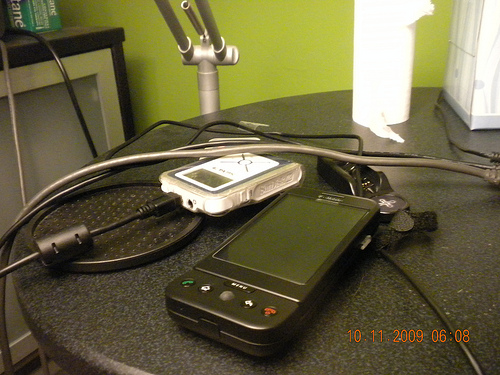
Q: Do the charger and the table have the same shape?
A: Yes, both the charger and the table are round.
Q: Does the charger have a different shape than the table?
A: No, both the charger and the table are round.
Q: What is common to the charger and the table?
A: The shape, both the charger and the table are round.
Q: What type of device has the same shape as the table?
A: The charger is the same shape as the table.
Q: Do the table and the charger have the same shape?
A: Yes, both the table and the charger are round.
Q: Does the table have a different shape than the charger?
A: No, both the table and the charger are round.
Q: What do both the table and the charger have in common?
A: The shape, both the table and the charger are round.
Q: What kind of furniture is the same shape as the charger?
A: The table is the same shape as the charger.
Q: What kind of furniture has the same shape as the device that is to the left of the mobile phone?
A: The table is the same shape as the charger.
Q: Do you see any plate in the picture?
A: No, there are no plates.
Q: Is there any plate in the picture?
A: No, there are no plates.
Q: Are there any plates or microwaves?
A: No, there are no plates or microwaves.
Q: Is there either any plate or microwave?
A: No, there are no plates or microwaves.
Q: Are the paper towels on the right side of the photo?
A: Yes, the paper towels are on the right of the image.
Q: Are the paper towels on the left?
A: No, the paper towels are on the right of the image.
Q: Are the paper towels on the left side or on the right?
A: The paper towels are on the right of the image.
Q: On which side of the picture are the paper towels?
A: The paper towels are on the right of the image.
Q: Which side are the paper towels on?
A: The paper towels are on the right of the image.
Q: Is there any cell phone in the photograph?
A: Yes, there is a cell phone.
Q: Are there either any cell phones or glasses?
A: Yes, there is a cell phone.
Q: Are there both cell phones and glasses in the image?
A: No, there is a cell phone but no glasses.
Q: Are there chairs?
A: No, there are no chairs.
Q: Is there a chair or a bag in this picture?
A: No, there are no chairs or bags.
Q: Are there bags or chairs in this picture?
A: No, there are no chairs or bags.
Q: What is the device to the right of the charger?
A: The device is a cell phone.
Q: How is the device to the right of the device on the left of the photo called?
A: The device is a cell phone.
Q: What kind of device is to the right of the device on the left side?
A: The device is a cell phone.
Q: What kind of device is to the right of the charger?
A: The device is a cell phone.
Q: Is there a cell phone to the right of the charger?
A: Yes, there is a cell phone to the right of the charger.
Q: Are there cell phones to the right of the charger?
A: Yes, there is a cell phone to the right of the charger.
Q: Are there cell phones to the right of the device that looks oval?
A: Yes, there is a cell phone to the right of the charger.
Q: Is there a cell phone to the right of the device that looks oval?
A: Yes, there is a cell phone to the right of the charger.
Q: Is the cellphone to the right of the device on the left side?
A: Yes, the cellphone is to the right of the charger.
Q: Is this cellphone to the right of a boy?
A: No, the cellphone is to the right of the charger.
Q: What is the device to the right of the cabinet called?
A: The device is a cell phone.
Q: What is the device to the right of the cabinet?
A: The device is a cell phone.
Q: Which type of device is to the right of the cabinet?
A: The device is a cell phone.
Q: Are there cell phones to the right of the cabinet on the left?
A: Yes, there is a cell phone to the right of the cabinet.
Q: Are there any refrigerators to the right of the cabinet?
A: No, there is a cell phone to the right of the cabinet.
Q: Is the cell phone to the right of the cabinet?
A: Yes, the cell phone is to the right of the cabinet.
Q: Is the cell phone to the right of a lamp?
A: No, the cell phone is to the right of the cabinet.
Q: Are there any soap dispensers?
A: No, there are no soap dispensers.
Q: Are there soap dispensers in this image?
A: No, there are no soap dispensers.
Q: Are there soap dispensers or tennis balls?
A: No, there are no soap dispensers or tennis balls.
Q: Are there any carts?
A: No, there are no carts.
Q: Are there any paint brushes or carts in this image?
A: No, there are no carts or paint brushes.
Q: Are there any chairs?
A: No, there are no chairs.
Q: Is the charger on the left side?
A: Yes, the charger is on the left of the image.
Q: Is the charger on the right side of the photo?
A: No, the charger is on the left of the image.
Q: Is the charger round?
A: Yes, the charger is round.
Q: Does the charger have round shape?
A: Yes, the charger is round.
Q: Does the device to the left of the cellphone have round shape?
A: Yes, the charger is round.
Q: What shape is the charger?
A: The charger is round.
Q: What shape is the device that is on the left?
A: The charger is round.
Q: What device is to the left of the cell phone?
A: The device is a charger.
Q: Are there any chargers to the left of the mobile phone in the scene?
A: Yes, there is a charger to the left of the mobile phone.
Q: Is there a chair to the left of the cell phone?
A: No, there is a charger to the left of the cell phone.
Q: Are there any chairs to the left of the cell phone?
A: No, there is a charger to the left of the cell phone.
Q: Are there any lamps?
A: No, there are no lamps.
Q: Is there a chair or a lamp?
A: No, there are no lamps or chairs.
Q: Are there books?
A: No, there are no books.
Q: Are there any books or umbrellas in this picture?
A: No, there are no books or umbrellas.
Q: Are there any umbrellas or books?
A: No, there are no books or umbrellas.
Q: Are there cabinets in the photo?
A: Yes, there is a cabinet.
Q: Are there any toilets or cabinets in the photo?
A: Yes, there is a cabinet.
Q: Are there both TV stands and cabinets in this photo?
A: No, there is a cabinet but no TV stands.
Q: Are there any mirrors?
A: No, there are no mirrors.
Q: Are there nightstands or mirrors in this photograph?
A: No, there are no mirrors or nightstands.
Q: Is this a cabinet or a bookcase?
A: This is a cabinet.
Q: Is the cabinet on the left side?
A: Yes, the cabinet is on the left of the image.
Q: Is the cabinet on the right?
A: No, the cabinet is on the left of the image.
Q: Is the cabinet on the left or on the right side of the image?
A: The cabinet is on the left of the image.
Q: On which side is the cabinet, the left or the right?
A: The cabinet is on the left of the image.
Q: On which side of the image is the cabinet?
A: The cabinet is on the left of the image.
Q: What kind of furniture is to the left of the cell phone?
A: The piece of furniture is a cabinet.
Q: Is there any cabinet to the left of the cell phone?
A: Yes, there is a cabinet to the left of the cell phone.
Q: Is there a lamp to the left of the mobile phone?
A: No, there is a cabinet to the left of the mobile phone.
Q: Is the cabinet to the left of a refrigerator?
A: No, the cabinet is to the left of a cell phone.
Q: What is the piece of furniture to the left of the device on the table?
A: The piece of furniture is a cabinet.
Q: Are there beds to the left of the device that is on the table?
A: No, there is a cabinet to the left of the device.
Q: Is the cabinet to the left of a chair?
A: No, the cabinet is to the left of the device.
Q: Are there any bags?
A: No, there are no bags.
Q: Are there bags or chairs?
A: No, there are no bags or chairs.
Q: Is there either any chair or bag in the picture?
A: No, there are no bags or chairs.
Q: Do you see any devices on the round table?
A: Yes, there is a device on the table.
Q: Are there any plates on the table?
A: No, there is a device on the table.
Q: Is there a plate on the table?
A: No, there is a device on the table.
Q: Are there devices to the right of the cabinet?
A: Yes, there is a device to the right of the cabinet.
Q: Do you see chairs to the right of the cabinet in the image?
A: No, there is a device to the right of the cabinet.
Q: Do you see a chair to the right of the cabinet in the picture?
A: No, there is a device to the right of the cabinet.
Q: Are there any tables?
A: Yes, there is a table.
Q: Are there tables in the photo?
A: Yes, there is a table.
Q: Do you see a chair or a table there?
A: Yes, there is a table.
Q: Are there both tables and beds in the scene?
A: No, there is a table but no beds.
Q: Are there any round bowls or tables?
A: Yes, there is a round table.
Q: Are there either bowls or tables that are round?
A: Yes, the table is round.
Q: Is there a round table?
A: Yes, there is a round table.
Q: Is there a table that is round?
A: Yes, there is a table that is round.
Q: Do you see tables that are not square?
A: Yes, there is a round table.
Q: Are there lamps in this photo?
A: No, there are no lamps.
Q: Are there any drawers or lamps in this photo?
A: No, there are no lamps or drawers.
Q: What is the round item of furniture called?
A: The piece of furniture is a table.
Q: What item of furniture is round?
A: The piece of furniture is a table.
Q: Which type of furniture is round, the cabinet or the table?
A: The table is round.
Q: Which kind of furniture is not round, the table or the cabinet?
A: The cabinet is not round.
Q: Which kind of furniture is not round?
A: The furniture is a cabinet.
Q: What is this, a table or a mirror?
A: This is a table.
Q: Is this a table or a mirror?
A: This is a table.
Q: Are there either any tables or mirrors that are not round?
A: No, there is a table but it is round.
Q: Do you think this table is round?
A: Yes, the table is round.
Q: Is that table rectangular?
A: No, the table is round.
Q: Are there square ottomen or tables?
A: No, there is a table but it is round.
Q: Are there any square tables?
A: No, there is a table but it is round.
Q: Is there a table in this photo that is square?
A: No, there is a table but it is round.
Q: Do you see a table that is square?
A: No, there is a table but it is round.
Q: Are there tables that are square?
A: No, there is a table but it is round.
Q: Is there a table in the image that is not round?
A: No, there is a table but it is round.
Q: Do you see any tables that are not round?
A: No, there is a table but it is round.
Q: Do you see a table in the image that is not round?
A: No, there is a table but it is round.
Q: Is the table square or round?
A: The table is round.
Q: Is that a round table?
A: Yes, that is a round table.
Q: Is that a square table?
A: No, that is a round table.